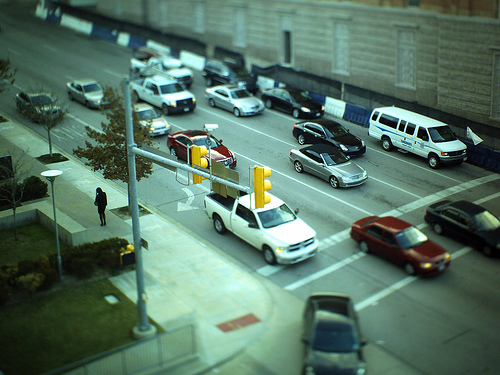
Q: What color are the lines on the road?
A: White.